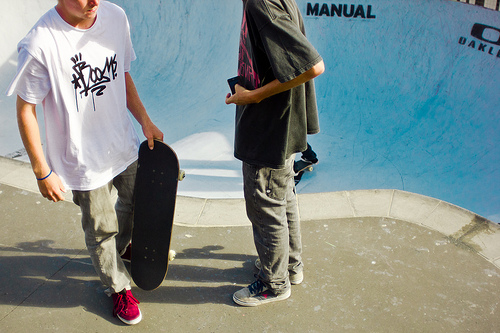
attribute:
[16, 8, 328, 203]
shirt — black, white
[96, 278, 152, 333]
shoe — pink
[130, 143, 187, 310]
skateboard — black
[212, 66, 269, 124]
phone — black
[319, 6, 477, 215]
ramp — blue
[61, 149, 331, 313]
pants — gray, gra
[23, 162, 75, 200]
bracelet — blue